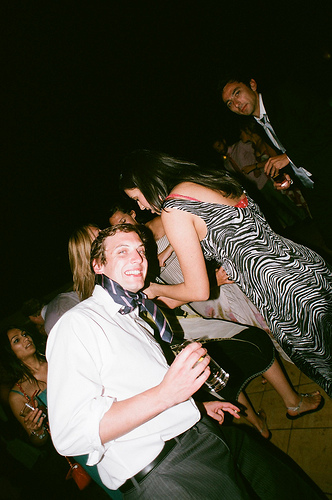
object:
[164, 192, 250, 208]
undergarment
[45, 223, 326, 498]
boy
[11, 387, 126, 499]
dress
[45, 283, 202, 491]
shirt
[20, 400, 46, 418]
cocktail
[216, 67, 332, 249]
man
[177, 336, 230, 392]
glass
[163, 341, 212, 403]
hand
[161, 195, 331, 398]
dress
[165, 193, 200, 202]
bra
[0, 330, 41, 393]
hair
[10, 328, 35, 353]
expression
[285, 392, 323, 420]
sandal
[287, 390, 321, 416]
foot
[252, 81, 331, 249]
suit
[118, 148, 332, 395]
girl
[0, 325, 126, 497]
girl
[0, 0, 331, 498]
crowd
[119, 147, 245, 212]
hair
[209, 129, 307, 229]
man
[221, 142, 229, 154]
beard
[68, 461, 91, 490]
bag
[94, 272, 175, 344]
tie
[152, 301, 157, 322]
stripes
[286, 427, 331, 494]
tiles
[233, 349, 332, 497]
floor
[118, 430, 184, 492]
belt